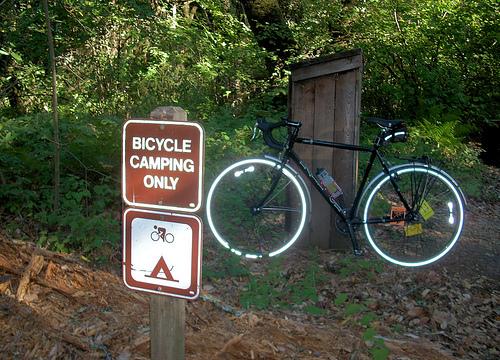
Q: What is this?
A: Bicycle.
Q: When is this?
A: Daytime.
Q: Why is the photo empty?
A: There is no one.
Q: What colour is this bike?
A: Black.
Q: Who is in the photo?
A: No one.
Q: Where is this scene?
A: On a bicycle trail in nature.